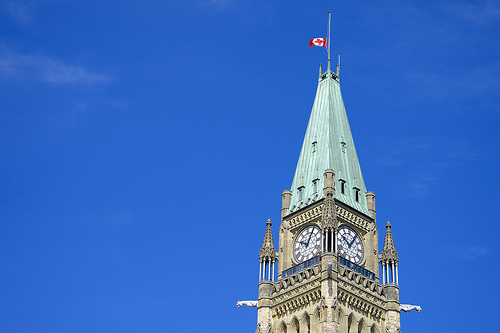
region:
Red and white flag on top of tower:
[308, 35, 325, 48]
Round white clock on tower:
[288, 223, 320, 263]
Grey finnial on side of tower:
[381, 220, 396, 301]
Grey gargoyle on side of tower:
[398, 303, 423, 313]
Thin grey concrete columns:
[380, 260, 398, 283]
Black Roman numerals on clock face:
[291, 221, 322, 263]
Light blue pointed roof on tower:
[283, 61, 373, 218]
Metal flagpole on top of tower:
[324, 11, 333, 73]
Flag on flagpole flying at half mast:
[307, 8, 344, 75]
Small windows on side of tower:
[341, 310, 379, 331]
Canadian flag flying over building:
[307, 33, 330, 52]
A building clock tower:
[282, 218, 374, 275]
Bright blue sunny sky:
[3, 2, 495, 330]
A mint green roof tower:
[289, 68, 372, 220]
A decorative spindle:
[259, 217, 276, 261]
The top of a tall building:
[233, 6, 419, 329]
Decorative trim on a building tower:
[263, 265, 387, 320]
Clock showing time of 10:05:
[289, 220, 324, 265]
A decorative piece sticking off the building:
[237, 298, 256, 305]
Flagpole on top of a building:
[326, 7, 333, 75]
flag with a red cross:
[309, 34, 330, 49]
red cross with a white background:
[309, 36, 329, 50]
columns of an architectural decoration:
[259, 257, 276, 282]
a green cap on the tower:
[290, 69, 373, 206]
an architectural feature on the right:
[379, 219, 401, 301]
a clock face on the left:
[289, 214, 323, 264]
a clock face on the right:
[335, 215, 366, 266]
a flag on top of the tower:
[309, 36, 329, 49]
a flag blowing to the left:
[311, 36, 326, 48]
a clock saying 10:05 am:
[288, 219, 323, 268]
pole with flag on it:
[301, 7, 338, 70]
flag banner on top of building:
[307, 31, 330, 52]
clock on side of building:
[285, 225, 324, 264]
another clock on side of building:
[334, 221, 364, 261]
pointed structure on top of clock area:
[290, 59, 371, 208]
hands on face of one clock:
[341, 232, 361, 245]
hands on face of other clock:
[288, 228, 323, 245]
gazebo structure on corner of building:
[381, 220, 400, 282]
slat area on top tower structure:
[351, 181, 365, 206]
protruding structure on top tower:
[337, 137, 351, 159]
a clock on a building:
[226, 94, 441, 298]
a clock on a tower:
[241, 166, 415, 307]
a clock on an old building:
[255, 168, 389, 330]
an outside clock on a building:
[280, 219, 380, 306]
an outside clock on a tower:
[271, 148, 383, 298]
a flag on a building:
[297, 2, 377, 102]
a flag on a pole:
[314, 8, 372, 95]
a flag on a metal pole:
[310, 11, 342, 98]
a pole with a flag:
[304, 18, 345, 76]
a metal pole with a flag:
[294, 5, 354, 98]